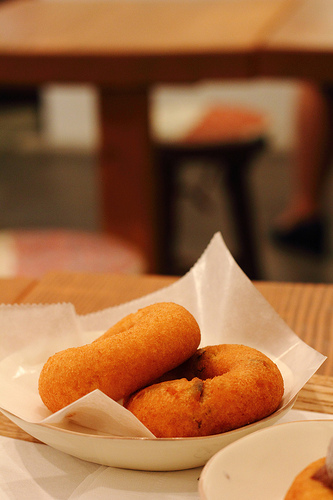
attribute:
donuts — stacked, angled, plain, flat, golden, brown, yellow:
[55, 309, 264, 441]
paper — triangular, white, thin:
[45, 238, 294, 451]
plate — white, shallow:
[14, 402, 313, 474]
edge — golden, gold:
[26, 414, 226, 459]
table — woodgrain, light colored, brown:
[37, 264, 330, 354]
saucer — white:
[10, 380, 291, 451]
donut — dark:
[145, 345, 267, 430]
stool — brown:
[148, 136, 263, 286]